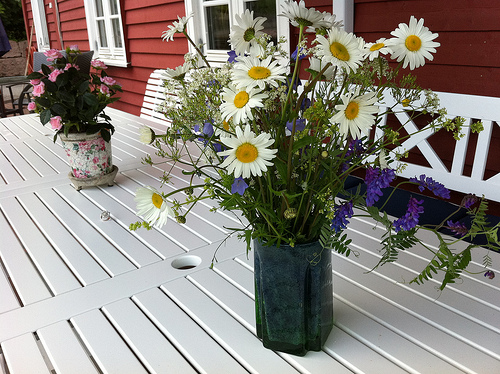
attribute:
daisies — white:
[141, 6, 448, 176]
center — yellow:
[329, 40, 348, 59]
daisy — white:
[314, 25, 367, 80]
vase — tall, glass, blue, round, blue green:
[247, 230, 349, 353]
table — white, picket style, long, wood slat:
[6, 98, 500, 373]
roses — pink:
[23, 35, 128, 145]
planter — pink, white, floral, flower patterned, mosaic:
[57, 120, 113, 181]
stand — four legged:
[68, 168, 119, 194]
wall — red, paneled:
[25, 2, 497, 164]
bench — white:
[139, 61, 464, 208]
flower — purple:
[410, 172, 454, 201]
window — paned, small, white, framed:
[87, 3, 128, 66]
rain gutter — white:
[328, 6, 354, 78]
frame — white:
[177, 0, 298, 68]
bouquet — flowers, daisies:
[135, 5, 499, 364]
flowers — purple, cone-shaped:
[134, 2, 497, 237]